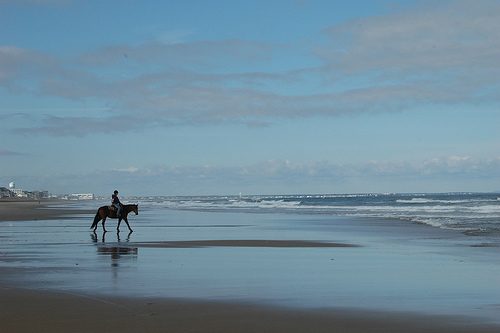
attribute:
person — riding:
[109, 187, 124, 216]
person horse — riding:
[87, 189, 141, 235]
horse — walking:
[87, 200, 142, 240]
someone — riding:
[104, 182, 129, 218]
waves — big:
[250, 197, 313, 208]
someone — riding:
[110, 189, 125, 219]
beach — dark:
[0, 0, 499, 331]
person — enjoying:
[110, 189, 123, 217]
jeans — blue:
[75, 197, 165, 232]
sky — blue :
[6, 6, 496, 200]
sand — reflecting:
[0, 198, 498, 330]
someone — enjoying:
[108, 189, 123, 216]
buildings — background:
[0, 180, 97, 202]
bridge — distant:
[204, 172, 410, 224]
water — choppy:
[166, 172, 386, 248]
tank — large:
[5, 176, 27, 198]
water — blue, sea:
[73, 190, 497, 238]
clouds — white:
[258, 42, 466, 118]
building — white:
[51, 158, 107, 218]